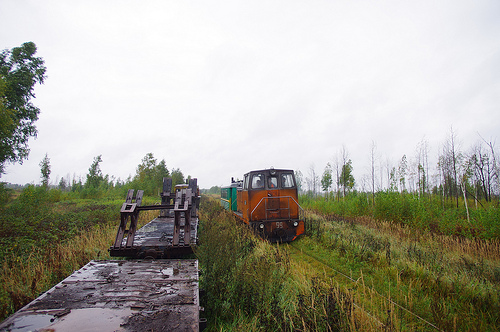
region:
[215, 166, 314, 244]
train on train tracks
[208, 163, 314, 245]
orange engine pulling green cars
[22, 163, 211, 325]
flatbed rail cars on siding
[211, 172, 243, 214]
green passenger car on train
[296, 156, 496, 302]
wild grass and bushes beside track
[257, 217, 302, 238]
headlights on orange engine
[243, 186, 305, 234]
railing on front of engine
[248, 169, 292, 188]
engineer and conductor on train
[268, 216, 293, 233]
number ninety-five on train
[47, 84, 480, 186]
cloudy overcast sky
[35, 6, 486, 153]
There are many clouds in the sky.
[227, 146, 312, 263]
The tractor is orange.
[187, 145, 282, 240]
The back is green.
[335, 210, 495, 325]
The grass is green.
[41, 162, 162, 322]
The device is brown.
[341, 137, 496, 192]
The trees are bare.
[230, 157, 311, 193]
The tractor has windows.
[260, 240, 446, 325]
The tractor is moving.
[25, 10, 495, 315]
They are in a farm.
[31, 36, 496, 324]
It is not sunny outside.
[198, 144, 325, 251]
A brown and green train in a field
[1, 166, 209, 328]
Gray metal train cars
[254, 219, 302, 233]
Two lights on the front of a train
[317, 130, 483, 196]
Small trees in a field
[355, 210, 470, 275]
A green grassy area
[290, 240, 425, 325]
Train tracks in a field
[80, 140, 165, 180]
Green trees in the background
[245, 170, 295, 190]
A train's windshield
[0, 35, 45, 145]
Green tree leaves on a tree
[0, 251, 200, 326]
A gray flat bed train car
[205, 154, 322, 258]
a train is on rails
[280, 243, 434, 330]
rail is cover with grass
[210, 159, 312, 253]
freight train runs on field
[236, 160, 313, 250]
front cabin of train is red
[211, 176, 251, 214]
car of train is green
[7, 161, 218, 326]
old structure of a train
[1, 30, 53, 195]
a tree next to metal structure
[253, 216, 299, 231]
two headlight of train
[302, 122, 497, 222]
trunks of trees without leaves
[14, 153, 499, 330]
field is covered with bushes and grass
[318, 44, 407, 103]
white cloud cover in sky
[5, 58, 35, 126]
green leaves of tree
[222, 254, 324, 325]
tall weeds on ground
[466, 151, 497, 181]
trees with no leaves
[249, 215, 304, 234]
lights on front of train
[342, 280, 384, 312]
train tracks in grass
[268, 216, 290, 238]
number on front of train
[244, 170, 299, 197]
windows on top of train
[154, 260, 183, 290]
puddle on flat surface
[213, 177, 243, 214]
green car on train